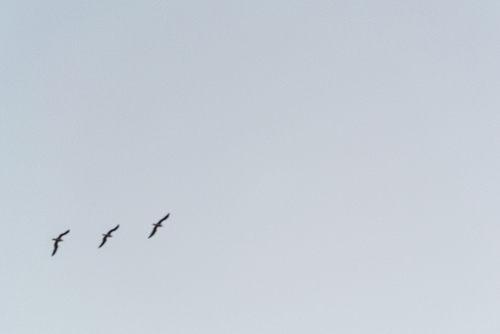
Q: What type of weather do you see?
A: It is clear.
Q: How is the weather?
A: It is clear.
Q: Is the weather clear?
A: Yes, it is clear.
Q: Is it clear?
A: Yes, it is clear.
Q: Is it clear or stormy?
A: It is clear.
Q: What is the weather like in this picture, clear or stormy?
A: It is clear.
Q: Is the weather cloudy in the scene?
A: No, it is clear.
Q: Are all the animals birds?
A: Yes, all the animals are birds.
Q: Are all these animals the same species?
A: Yes, all the animals are birds.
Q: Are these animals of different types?
A: No, all the animals are birds.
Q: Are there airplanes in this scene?
A: No, there are no airplanes.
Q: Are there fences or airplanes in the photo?
A: No, there are no airplanes or fences.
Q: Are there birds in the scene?
A: Yes, there are birds.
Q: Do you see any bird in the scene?
A: Yes, there are birds.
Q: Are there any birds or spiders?
A: Yes, there are birds.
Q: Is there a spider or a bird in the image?
A: Yes, there are birds.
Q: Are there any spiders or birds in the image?
A: Yes, there are birds.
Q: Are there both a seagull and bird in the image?
A: No, there are birds but no seagulls.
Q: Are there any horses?
A: No, there are no horses.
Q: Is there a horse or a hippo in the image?
A: No, there are no horses or hippoes.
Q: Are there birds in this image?
A: Yes, there is a bird.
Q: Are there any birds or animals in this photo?
A: Yes, there is a bird.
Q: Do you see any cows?
A: No, there are no cows.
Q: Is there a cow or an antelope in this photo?
A: No, there are no cows or antelopes.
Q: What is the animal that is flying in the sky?
A: The animal is a bird.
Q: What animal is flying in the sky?
A: The animal is a bird.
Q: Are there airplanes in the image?
A: No, there are no airplanes.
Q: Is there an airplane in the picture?
A: No, there are no airplanes.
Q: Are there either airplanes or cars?
A: No, there are no airplanes or cars.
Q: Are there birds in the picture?
A: Yes, there is a bird.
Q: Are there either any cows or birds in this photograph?
A: Yes, there is a bird.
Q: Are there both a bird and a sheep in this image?
A: No, there is a bird but no sheep.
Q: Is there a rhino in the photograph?
A: No, there are no rhinos.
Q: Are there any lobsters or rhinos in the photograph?
A: No, there are no rhinos or lobsters.